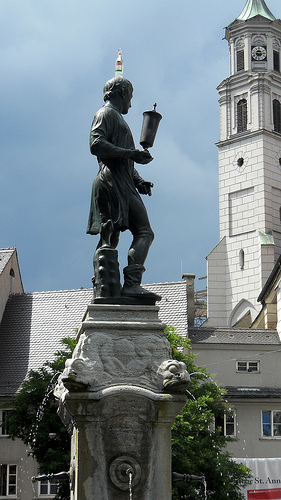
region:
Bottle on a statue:
[95, 46, 137, 72]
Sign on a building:
[228, 449, 279, 492]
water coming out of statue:
[20, 454, 82, 494]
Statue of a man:
[77, 73, 144, 335]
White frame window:
[7, 462, 14, 496]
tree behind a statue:
[188, 422, 247, 483]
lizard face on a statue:
[58, 357, 104, 405]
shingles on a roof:
[38, 285, 101, 331]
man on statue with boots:
[72, 236, 160, 312]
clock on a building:
[231, 21, 277, 77]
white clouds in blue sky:
[9, 11, 47, 50]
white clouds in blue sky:
[13, 60, 61, 100]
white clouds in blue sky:
[20, 117, 71, 182]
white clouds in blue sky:
[23, 188, 66, 219]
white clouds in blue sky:
[23, 224, 62, 268]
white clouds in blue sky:
[156, 187, 193, 221]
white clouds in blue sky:
[169, 229, 190, 253]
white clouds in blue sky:
[124, 22, 179, 73]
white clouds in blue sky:
[66, 24, 108, 50]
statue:
[70, 80, 181, 304]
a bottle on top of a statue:
[114, 45, 125, 81]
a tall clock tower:
[189, 3, 280, 257]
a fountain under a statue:
[57, 298, 232, 498]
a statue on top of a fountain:
[18, 44, 200, 498]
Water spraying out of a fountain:
[154, 356, 257, 470]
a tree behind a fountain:
[23, 314, 261, 499]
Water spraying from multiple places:
[12, 356, 250, 497]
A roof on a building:
[0, 295, 66, 381]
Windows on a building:
[212, 401, 279, 442]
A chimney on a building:
[179, 269, 199, 332]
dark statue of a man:
[87, 77, 164, 302]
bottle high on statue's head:
[102, 47, 132, 115]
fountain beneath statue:
[51, 75, 189, 498]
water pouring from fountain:
[171, 469, 207, 498]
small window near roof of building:
[189, 328, 280, 387]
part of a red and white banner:
[228, 456, 278, 498]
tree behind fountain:
[2, 305, 252, 496]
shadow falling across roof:
[1, 291, 53, 393]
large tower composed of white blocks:
[199, 1, 280, 327]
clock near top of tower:
[222, 0, 279, 69]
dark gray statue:
[89, 66, 158, 279]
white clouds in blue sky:
[6, 39, 30, 75]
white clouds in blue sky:
[8, 91, 52, 148]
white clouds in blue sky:
[56, 16, 100, 65]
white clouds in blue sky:
[174, 184, 190, 228]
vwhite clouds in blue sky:
[35, 230, 72, 267]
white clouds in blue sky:
[156, 27, 223, 76]